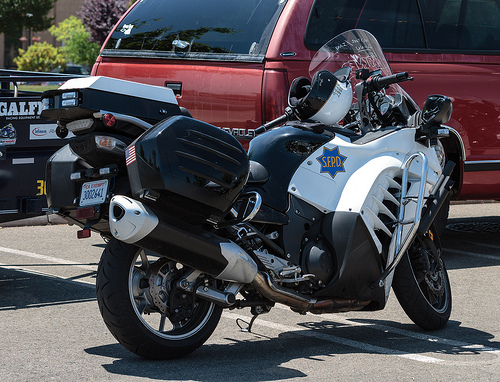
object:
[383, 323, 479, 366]
white lines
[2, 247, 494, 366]
line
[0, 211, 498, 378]
pavement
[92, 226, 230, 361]
tire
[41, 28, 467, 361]
bike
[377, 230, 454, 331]
tire